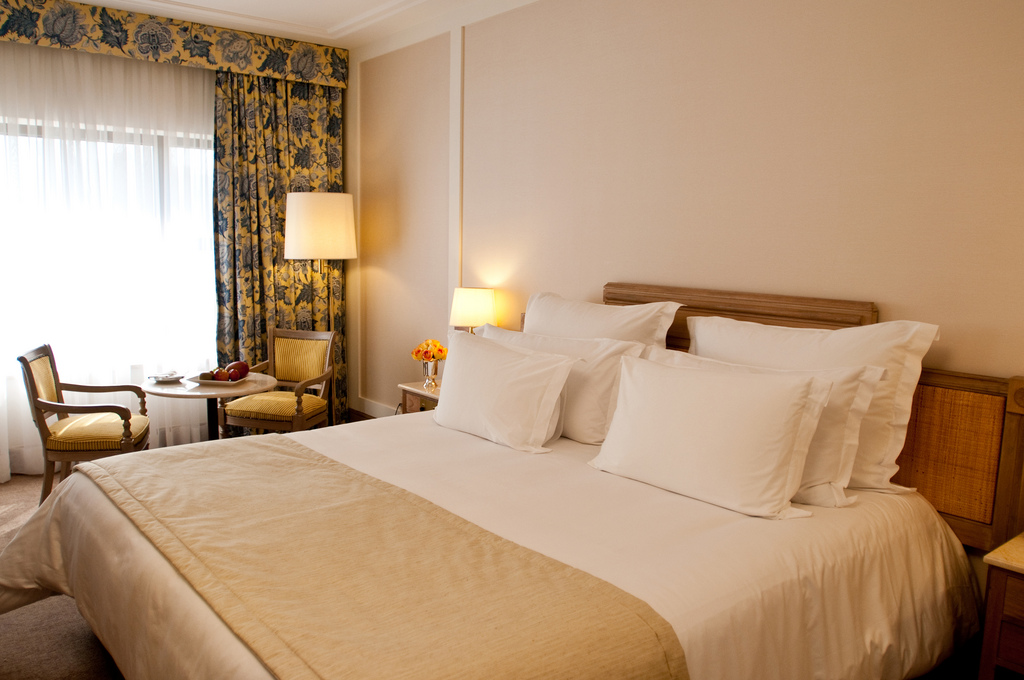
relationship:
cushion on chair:
[47, 405, 150, 448] [16, 345, 153, 510]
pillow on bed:
[590, 351, 832, 517] [1, 272, 978, 674]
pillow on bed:
[641, 341, 890, 510] [1, 272, 978, 674]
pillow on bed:
[681, 315, 939, 494] [1, 272, 978, 674]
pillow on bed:
[432, 326, 587, 456] [1, 272, 978, 674]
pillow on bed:
[466, 319, 653, 451] [1, 272, 978, 674]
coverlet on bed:
[69, 406, 989, 680] [1, 272, 978, 674]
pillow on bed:
[429, 328, 579, 454] [1, 272, 978, 674]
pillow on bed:
[584, 352, 838, 523] [1, 272, 978, 674]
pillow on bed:
[518, 286, 687, 360] [1, 272, 978, 674]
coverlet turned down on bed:
[172, 442, 572, 673] [57, 288, 1010, 662]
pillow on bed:
[427, 323, 580, 461] [1, 272, 978, 674]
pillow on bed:
[517, 282, 683, 371] [1, 272, 978, 674]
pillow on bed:
[582, 343, 830, 528] [1, 272, 978, 674]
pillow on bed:
[671, 300, 944, 496] [1, 272, 978, 674]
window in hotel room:
[1, 1, 352, 485] [1, 1, 1015, 669]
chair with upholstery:
[12, 326, 159, 508] [27, 362, 149, 436]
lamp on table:
[259, 177, 386, 343] [396, 376, 436, 407]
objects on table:
[137, 358, 204, 396] [166, 340, 264, 443]